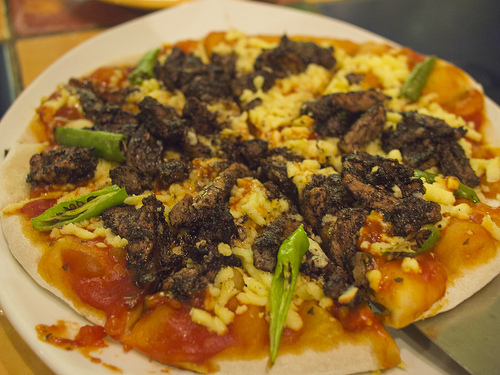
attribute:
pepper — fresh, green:
[264, 222, 309, 362]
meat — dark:
[61, 61, 438, 318]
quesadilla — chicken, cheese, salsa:
[4, 4, 499, 358]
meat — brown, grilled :
[346, 145, 394, 192]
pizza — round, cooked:
[201, 24, 379, 185]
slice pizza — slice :
[283, 163, 424, 230]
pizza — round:
[159, 78, 338, 244]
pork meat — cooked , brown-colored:
[278, 82, 484, 271]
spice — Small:
[377, 192, 457, 267]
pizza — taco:
[0, 28, 499, 373]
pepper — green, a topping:
[398, 49, 435, 104]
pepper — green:
[32, 184, 125, 231]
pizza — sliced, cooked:
[169, 192, 342, 322]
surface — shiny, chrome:
[421, 299, 498, 361]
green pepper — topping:
[397, 51, 439, 102]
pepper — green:
[269, 224, 306, 364]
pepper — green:
[403, 52, 438, 103]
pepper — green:
[411, 169, 478, 203]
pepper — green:
[414, 225, 441, 252]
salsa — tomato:
[154, 306, 219, 346]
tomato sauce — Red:
[68, 250, 128, 313]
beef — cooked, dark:
[50, 29, 478, 302]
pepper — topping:
[270, 50, 498, 325]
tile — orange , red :
[12, 25, 113, 95]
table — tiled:
[0, 25, 497, 374]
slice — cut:
[123, 153, 397, 373]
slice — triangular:
[206, 17, 356, 177]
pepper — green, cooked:
[248, 219, 318, 372]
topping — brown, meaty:
[116, 176, 248, 306]